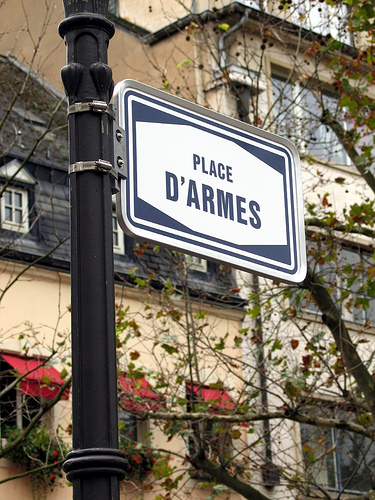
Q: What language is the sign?
A: French.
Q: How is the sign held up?
A: On pole.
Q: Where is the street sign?
A: On a pole.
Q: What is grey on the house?
A: The roof.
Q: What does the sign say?
A: Place D'Armes.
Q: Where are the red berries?
A: On the tree.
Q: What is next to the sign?
A: A tree with lots of branches and leaves.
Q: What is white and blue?
A: A sign.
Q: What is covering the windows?
A: Red canopies.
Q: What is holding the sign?
A: A black pole.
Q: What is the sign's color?
A: Blue and white.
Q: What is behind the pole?
A: Trees.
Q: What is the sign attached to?
A: A street pole.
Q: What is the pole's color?
A: Black.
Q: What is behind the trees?
A: Buildings.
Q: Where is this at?
A: On a street corner.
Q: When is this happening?
A: During the day time.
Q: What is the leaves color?
A: Green.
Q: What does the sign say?
A: Place D'Armes.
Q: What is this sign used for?
A: Directions.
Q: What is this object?
A: A street sign.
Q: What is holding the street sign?
A: A street pole.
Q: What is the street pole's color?
A: Black.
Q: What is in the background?
A: Buildings.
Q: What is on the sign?
A: Place D'Armes.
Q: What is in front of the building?
A: Trees.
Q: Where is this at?
A: Next to a street corner.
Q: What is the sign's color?
A: White and blue.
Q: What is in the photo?
A: Streetsign.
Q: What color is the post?
A: Black.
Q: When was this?
A: Daytime.